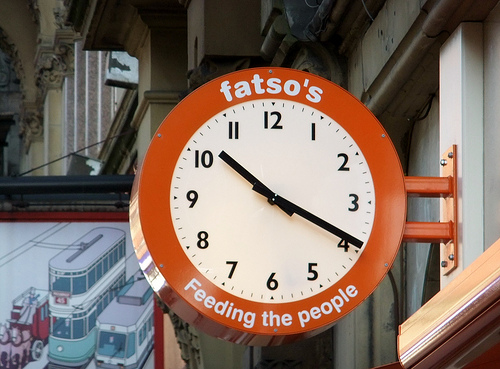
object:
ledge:
[396, 237, 500, 369]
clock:
[127, 66, 409, 350]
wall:
[416, 0, 499, 293]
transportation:
[2, 219, 155, 368]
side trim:
[394, 237, 500, 367]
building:
[0, 0, 500, 369]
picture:
[0, 221, 153, 368]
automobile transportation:
[0, 223, 156, 368]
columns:
[20, 37, 166, 182]